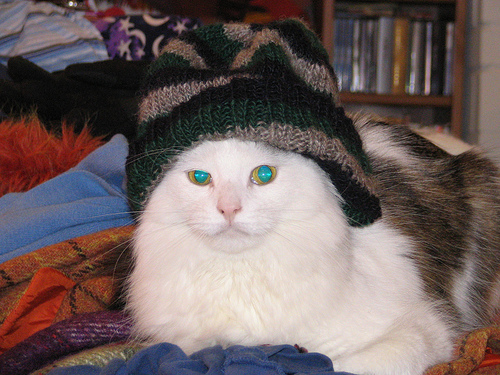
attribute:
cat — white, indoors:
[174, 119, 463, 320]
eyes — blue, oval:
[186, 158, 289, 238]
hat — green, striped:
[140, 26, 361, 173]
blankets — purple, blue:
[163, 342, 237, 375]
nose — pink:
[216, 196, 234, 218]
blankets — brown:
[70, 81, 105, 120]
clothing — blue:
[39, 177, 104, 233]